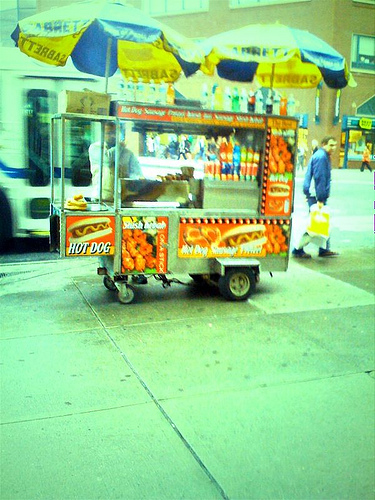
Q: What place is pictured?
A: It is a sidewalk.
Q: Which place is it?
A: It is a sidewalk.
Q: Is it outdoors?
A: Yes, it is outdoors.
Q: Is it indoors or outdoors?
A: It is outdoors.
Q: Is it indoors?
A: No, it is outdoors.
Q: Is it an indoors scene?
A: No, it is outdoors.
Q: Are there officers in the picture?
A: No, there are no officers.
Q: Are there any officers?
A: No, there are no officers.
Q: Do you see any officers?
A: No, there are no officers.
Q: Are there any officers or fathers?
A: No, there are no officers or fathers.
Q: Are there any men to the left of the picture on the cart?
A: Yes, there is a man to the left of the picture.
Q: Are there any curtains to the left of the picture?
A: No, there is a man to the left of the picture.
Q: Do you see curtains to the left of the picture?
A: No, there is a man to the left of the picture.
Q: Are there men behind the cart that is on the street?
A: Yes, there is a man behind the cart.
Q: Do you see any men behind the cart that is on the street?
A: Yes, there is a man behind the cart.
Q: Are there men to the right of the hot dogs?
A: Yes, there is a man to the right of the hot dogs.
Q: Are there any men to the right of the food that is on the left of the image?
A: Yes, there is a man to the right of the hot dogs.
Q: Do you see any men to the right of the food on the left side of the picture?
A: Yes, there is a man to the right of the hot dogs.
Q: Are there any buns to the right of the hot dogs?
A: No, there is a man to the right of the hot dogs.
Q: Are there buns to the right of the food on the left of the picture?
A: No, there is a man to the right of the hot dogs.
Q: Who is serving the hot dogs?
A: The man is serving the hot dogs.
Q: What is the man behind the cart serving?
A: The man is serving hot dogs.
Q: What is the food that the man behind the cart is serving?
A: The food is hot dogs.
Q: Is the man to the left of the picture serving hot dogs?
A: Yes, the man is serving hot dogs.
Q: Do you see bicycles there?
A: No, there are no bicycles.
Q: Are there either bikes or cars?
A: No, there are no bikes or cars.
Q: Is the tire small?
A: Yes, the tire is small.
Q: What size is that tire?
A: The tire is small.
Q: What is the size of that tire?
A: The tire is small.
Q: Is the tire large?
A: No, the tire is small.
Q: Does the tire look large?
A: No, the tire is small.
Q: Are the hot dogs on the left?
A: Yes, the hot dogs are on the left of the image.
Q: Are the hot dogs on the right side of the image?
A: No, the hot dogs are on the left of the image.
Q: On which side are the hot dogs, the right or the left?
A: The hot dogs are on the left of the image.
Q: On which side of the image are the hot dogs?
A: The hot dogs are on the left of the image.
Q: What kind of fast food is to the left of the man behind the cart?
A: The food is hot dogs.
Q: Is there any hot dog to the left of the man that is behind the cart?
A: Yes, there are hot dogs to the left of the man.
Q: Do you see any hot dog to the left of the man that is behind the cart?
A: Yes, there are hot dogs to the left of the man.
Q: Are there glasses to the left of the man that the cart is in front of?
A: No, there are hot dogs to the left of the man.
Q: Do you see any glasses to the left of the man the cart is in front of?
A: No, there are hot dogs to the left of the man.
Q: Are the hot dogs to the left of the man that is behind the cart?
A: Yes, the hot dogs are to the left of the man.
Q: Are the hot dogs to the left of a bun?
A: No, the hot dogs are to the left of the man.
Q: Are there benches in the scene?
A: No, there are no benches.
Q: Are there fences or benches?
A: No, there are no benches or fences.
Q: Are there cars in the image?
A: No, there are no cars.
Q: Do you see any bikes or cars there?
A: No, there are no cars or bikes.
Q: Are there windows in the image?
A: Yes, there is a window.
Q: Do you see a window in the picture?
A: Yes, there is a window.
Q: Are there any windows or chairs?
A: Yes, there is a window.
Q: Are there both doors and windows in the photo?
A: No, there is a window but no doors.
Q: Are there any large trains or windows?
A: Yes, there is a large window.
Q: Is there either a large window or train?
A: Yes, there is a large window.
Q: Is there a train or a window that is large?
A: Yes, the window is large.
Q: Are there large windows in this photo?
A: Yes, there is a large window.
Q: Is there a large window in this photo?
A: Yes, there is a large window.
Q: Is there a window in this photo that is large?
A: Yes, there is a window that is large.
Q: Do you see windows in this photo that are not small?
A: Yes, there is a large window.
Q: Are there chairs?
A: No, there are no chairs.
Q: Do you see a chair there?
A: No, there are no chairs.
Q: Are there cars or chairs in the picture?
A: No, there are no chairs or cars.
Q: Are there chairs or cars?
A: No, there are no chairs or cars.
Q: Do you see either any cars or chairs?
A: No, there are no chairs or cars.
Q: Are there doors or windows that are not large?
A: No, there is a window but it is large.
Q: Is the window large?
A: Yes, the window is large.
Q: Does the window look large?
A: Yes, the window is large.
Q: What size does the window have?
A: The window has large size.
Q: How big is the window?
A: The window is large.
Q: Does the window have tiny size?
A: No, the window is large.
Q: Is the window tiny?
A: No, the window is large.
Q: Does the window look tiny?
A: No, the window is large.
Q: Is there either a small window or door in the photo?
A: No, there is a window but it is large.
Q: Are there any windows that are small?
A: No, there is a window but it is large.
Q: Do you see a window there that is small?
A: No, there is a window but it is large.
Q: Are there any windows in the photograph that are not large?
A: No, there is a window but it is large.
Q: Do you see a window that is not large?
A: No, there is a window but it is large.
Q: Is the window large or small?
A: The window is large.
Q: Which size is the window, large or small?
A: The window is large.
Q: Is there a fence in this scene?
A: No, there are no fences.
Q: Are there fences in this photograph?
A: No, there are no fences.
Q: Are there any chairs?
A: No, there are no chairs.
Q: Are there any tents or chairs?
A: No, there are no chairs or tents.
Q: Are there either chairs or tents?
A: No, there are no chairs or tents.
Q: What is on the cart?
A: The picture is on the cart.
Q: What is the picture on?
A: The picture is on the cart.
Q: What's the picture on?
A: The picture is on the cart.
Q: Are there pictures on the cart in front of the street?
A: Yes, there is a picture on the cart.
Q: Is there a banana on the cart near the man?
A: No, there is a picture on the cart.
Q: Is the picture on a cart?
A: Yes, the picture is on a cart.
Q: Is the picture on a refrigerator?
A: No, the picture is on a cart.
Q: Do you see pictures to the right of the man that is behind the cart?
A: Yes, there is a picture to the right of the man.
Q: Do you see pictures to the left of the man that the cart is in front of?
A: No, the picture is to the right of the man.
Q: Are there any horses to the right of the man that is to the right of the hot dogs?
A: No, there is a picture to the right of the man.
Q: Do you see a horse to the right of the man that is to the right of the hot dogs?
A: No, there is a picture to the right of the man.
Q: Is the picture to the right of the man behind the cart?
A: Yes, the picture is to the right of the man.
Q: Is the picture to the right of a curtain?
A: No, the picture is to the right of the man.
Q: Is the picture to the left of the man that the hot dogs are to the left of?
A: No, the picture is to the right of the man.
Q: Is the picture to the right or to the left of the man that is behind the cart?
A: The picture is to the right of the man.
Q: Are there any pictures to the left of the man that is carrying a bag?
A: Yes, there is a picture to the left of the man.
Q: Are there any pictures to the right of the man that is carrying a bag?
A: No, the picture is to the left of the man.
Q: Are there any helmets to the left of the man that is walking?
A: No, there is a picture to the left of the man.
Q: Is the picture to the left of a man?
A: Yes, the picture is to the left of a man.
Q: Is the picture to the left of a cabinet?
A: No, the picture is to the left of a man.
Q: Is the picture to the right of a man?
A: No, the picture is to the left of a man.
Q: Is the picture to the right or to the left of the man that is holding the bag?
A: The picture is to the left of the man.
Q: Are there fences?
A: No, there are no fences.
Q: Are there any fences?
A: No, there are no fences.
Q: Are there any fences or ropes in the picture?
A: No, there are no fences or ropes.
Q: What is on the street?
A: The cart is on the street.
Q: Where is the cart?
A: The cart is on the street.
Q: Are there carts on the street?
A: Yes, there is a cart on the street.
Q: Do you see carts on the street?
A: Yes, there is a cart on the street.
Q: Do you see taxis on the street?
A: No, there is a cart on the street.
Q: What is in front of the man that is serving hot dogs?
A: The cart is in front of the man.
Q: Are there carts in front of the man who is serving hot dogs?
A: Yes, there is a cart in front of the man.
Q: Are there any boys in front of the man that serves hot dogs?
A: No, there is a cart in front of the man.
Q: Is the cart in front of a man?
A: Yes, the cart is in front of a man.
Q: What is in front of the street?
A: The cart is in front of the street.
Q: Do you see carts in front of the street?
A: Yes, there is a cart in front of the street.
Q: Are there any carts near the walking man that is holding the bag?
A: Yes, there is a cart near the man.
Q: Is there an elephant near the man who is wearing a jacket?
A: No, there is a cart near the man.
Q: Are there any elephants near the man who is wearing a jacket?
A: No, there is a cart near the man.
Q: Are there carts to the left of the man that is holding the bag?
A: Yes, there is a cart to the left of the man.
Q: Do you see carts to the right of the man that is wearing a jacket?
A: No, the cart is to the left of the man.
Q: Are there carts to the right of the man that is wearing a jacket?
A: No, the cart is to the left of the man.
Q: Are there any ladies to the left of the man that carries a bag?
A: No, there is a cart to the left of the man.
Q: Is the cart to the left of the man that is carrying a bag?
A: Yes, the cart is to the left of the man.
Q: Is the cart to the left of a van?
A: No, the cart is to the left of the man.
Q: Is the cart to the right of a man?
A: No, the cart is to the left of a man.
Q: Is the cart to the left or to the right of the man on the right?
A: The cart is to the left of the man.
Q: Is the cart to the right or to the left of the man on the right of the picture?
A: The cart is to the left of the man.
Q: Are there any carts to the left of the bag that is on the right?
A: Yes, there is a cart to the left of the bag.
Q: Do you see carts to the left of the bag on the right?
A: Yes, there is a cart to the left of the bag.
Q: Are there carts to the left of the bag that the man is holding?
A: Yes, there is a cart to the left of the bag.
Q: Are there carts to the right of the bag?
A: No, the cart is to the left of the bag.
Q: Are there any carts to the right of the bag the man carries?
A: No, the cart is to the left of the bag.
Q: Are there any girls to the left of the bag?
A: No, there is a cart to the left of the bag.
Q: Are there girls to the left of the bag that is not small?
A: No, there is a cart to the left of the bag.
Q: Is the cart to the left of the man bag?
A: Yes, the cart is to the left of the bag.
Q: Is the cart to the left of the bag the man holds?
A: Yes, the cart is to the left of the bag.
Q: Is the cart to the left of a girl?
A: No, the cart is to the left of the bag.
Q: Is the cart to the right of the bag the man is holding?
A: No, the cart is to the left of the bag.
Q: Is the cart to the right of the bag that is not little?
A: No, the cart is to the left of the bag.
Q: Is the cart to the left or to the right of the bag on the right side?
A: The cart is to the left of the bag.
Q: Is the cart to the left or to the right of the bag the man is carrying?
A: The cart is to the left of the bag.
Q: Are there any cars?
A: No, there are no cars.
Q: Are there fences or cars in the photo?
A: No, there are no cars or fences.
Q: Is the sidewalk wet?
A: Yes, the sidewalk is wet.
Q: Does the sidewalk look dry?
A: No, the sidewalk is wet.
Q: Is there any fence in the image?
A: No, there are no fences.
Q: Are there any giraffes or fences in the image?
A: No, there are no fences or giraffes.